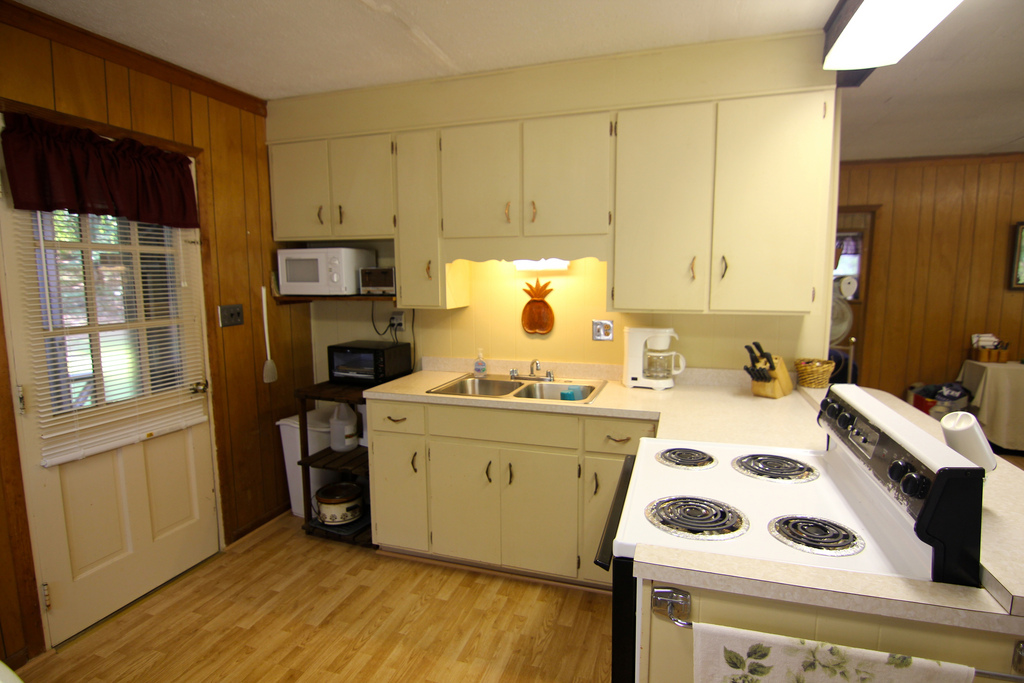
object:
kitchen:
[0, 0, 1024, 683]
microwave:
[276, 246, 377, 296]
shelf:
[276, 294, 397, 307]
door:
[0, 122, 227, 651]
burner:
[731, 453, 819, 483]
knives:
[762, 351, 776, 369]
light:
[512, 258, 570, 271]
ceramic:
[520, 278, 556, 335]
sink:
[514, 379, 609, 405]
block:
[750, 353, 793, 400]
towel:
[679, 617, 978, 683]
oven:
[591, 434, 1024, 683]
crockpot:
[310, 481, 364, 526]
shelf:
[295, 376, 378, 406]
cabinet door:
[438, 119, 525, 240]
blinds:
[9, 206, 212, 469]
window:
[28, 202, 192, 417]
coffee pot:
[621, 324, 689, 392]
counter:
[362, 369, 828, 451]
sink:
[425, 372, 526, 398]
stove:
[766, 513, 867, 557]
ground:
[0, 508, 610, 682]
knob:
[191, 381, 210, 394]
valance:
[0, 109, 206, 229]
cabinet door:
[706, 87, 840, 314]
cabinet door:
[611, 100, 718, 311]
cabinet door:
[394, 128, 441, 308]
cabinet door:
[269, 138, 334, 239]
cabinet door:
[372, 434, 429, 553]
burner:
[643, 495, 752, 542]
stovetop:
[610, 435, 935, 584]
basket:
[792, 357, 836, 389]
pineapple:
[518, 271, 557, 337]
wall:
[309, 239, 810, 414]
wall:
[0, 0, 323, 674]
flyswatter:
[258, 284, 282, 385]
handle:
[718, 255, 729, 280]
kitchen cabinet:
[707, 88, 838, 313]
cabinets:
[364, 398, 659, 588]